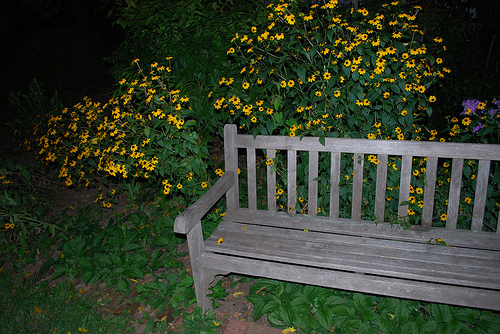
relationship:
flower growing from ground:
[21, 0, 499, 221] [3, 155, 482, 295]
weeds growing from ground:
[6, 168, 498, 332] [4, 199, 484, 330]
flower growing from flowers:
[21, 0, 499, 221] [455, 94, 484, 129]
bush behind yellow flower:
[139, 20, 229, 94] [165, 53, 176, 61]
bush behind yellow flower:
[139, 20, 229, 94] [169, 86, 181, 96]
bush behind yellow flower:
[139, 20, 229, 94] [214, 71, 225, 83]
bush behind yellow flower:
[139, 20, 229, 94] [226, 48, 240, 60]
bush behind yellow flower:
[139, 20, 229, 94] [287, 13, 295, 25]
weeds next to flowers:
[0, 168, 500, 334] [51, 72, 195, 177]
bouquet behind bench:
[51, 5, 478, 218] [171, 114, 498, 320]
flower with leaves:
[21, 0, 499, 221] [145, 117, 204, 175]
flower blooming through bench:
[45, 109, 107, 179] [174, 121, 484, 288]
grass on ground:
[93, 240, 145, 287] [100, 285, 157, 328]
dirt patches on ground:
[16, 164, 265, 332] [4, 125, 495, 332]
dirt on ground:
[213, 291, 291, 331] [74, 257, 144, 310]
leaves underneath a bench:
[253, 276, 458, 332] [171, 114, 498, 320]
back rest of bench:
[223, 122, 497, 246] [171, 114, 498, 320]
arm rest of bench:
[172, 173, 236, 233] [171, 114, 498, 320]